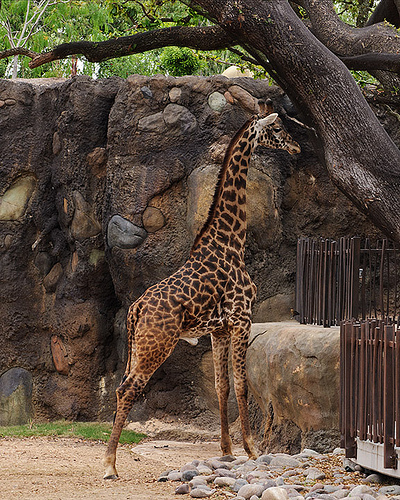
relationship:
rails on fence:
[306, 235, 386, 275] [295, 236, 379, 331]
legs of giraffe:
[109, 353, 256, 454] [135, 108, 332, 423]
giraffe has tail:
[135, 108, 332, 423] [108, 309, 153, 367]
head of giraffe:
[230, 107, 281, 129] [135, 108, 332, 423]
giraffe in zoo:
[135, 108, 332, 423] [51, 32, 328, 414]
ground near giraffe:
[20, 393, 247, 499] [135, 108, 332, 423]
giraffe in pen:
[135, 108, 332, 423] [29, 23, 380, 384]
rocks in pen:
[27, 103, 167, 266] [29, 23, 380, 384]